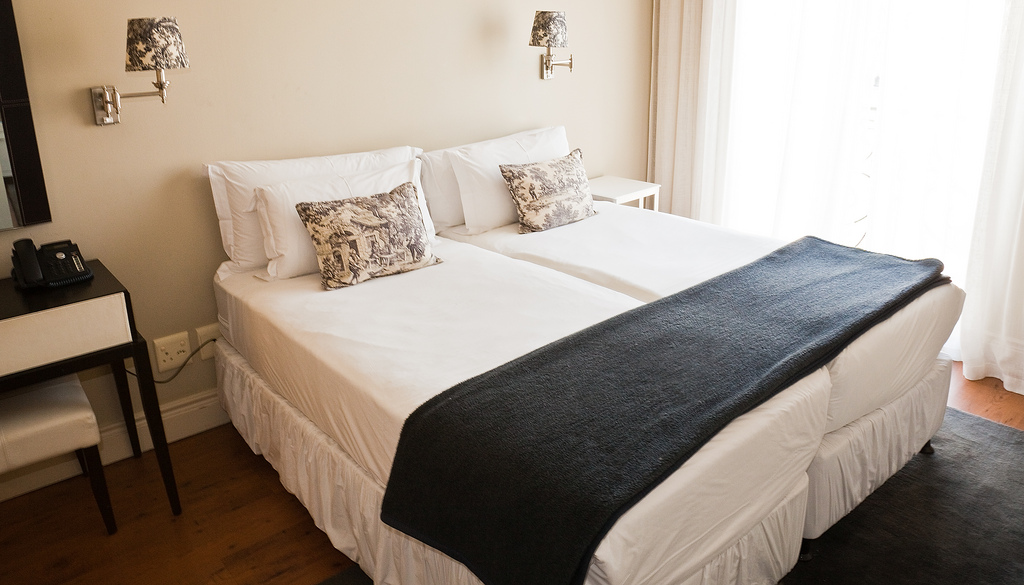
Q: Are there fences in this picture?
A: No, there are no fences.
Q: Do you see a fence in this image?
A: No, there are no fences.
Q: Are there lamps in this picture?
A: Yes, there is a lamp.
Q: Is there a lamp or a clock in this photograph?
A: Yes, there is a lamp.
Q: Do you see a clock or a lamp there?
A: Yes, there is a lamp.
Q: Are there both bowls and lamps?
A: No, there is a lamp but no bowls.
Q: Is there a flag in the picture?
A: No, there are no flags.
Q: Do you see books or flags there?
A: No, there are no flags or books.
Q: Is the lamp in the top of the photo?
A: Yes, the lamp is in the top of the image.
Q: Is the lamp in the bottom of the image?
A: No, the lamp is in the top of the image.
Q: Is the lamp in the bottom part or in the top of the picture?
A: The lamp is in the top of the image.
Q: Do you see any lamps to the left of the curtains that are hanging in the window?
A: Yes, there is a lamp to the left of the curtains.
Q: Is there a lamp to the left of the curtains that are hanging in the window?
A: Yes, there is a lamp to the left of the curtains.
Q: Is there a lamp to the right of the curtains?
A: No, the lamp is to the left of the curtains.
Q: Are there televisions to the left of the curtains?
A: No, there is a lamp to the left of the curtains.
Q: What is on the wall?
A: The lamp is on the wall.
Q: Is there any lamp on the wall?
A: Yes, there is a lamp on the wall.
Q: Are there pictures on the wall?
A: No, there is a lamp on the wall.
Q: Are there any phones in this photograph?
A: Yes, there is a phone.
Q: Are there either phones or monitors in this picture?
A: Yes, there is a phone.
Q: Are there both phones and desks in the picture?
A: Yes, there are both a phone and a desk.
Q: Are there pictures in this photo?
A: No, there are no pictures.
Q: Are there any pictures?
A: No, there are no pictures.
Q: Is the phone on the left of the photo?
A: Yes, the phone is on the left of the image.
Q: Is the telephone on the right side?
A: No, the telephone is on the left of the image.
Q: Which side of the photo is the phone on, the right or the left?
A: The phone is on the left of the image.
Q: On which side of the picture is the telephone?
A: The telephone is on the left of the image.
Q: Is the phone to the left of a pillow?
A: Yes, the phone is to the left of a pillow.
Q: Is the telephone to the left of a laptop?
A: No, the telephone is to the left of a pillow.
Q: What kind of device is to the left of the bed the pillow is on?
A: The device is a phone.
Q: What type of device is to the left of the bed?
A: The device is a phone.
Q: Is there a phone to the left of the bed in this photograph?
A: Yes, there is a phone to the left of the bed.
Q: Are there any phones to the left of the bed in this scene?
A: Yes, there is a phone to the left of the bed.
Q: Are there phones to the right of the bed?
A: No, the phone is to the left of the bed.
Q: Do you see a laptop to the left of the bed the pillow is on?
A: No, there is a phone to the left of the bed.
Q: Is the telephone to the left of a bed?
A: Yes, the telephone is to the left of a bed.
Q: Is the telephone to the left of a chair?
A: No, the telephone is to the left of a bed.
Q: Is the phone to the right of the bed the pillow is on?
A: No, the phone is to the left of the bed.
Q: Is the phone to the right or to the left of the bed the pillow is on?
A: The phone is to the left of the bed.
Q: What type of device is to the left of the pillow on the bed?
A: The device is a phone.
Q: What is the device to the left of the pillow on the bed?
A: The device is a phone.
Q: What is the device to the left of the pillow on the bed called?
A: The device is a phone.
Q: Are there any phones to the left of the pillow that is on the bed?
A: Yes, there is a phone to the left of the pillow.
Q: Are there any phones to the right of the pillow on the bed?
A: No, the phone is to the left of the pillow.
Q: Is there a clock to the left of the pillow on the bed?
A: No, there is a phone to the left of the pillow.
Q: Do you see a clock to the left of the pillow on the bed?
A: No, there is a phone to the left of the pillow.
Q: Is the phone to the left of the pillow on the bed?
A: Yes, the phone is to the left of the pillow.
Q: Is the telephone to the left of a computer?
A: No, the telephone is to the left of the pillow.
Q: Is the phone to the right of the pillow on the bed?
A: No, the phone is to the left of the pillow.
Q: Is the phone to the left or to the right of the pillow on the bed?
A: The phone is to the left of the pillow.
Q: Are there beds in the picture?
A: Yes, there is a bed.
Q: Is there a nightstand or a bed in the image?
A: Yes, there is a bed.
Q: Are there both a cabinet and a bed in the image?
A: No, there is a bed but no cabinets.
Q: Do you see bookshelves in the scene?
A: No, there are no bookshelves.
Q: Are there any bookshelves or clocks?
A: No, there are no bookshelves or clocks.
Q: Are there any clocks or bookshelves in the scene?
A: No, there are no bookshelves or clocks.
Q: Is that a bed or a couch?
A: That is a bed.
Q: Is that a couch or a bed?
A: That is a bed.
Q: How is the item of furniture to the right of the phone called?
A: The piece of furniture is a bed.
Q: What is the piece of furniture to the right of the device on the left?
A: The piece of furniture is a bed.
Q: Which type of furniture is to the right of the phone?
A: The piece of furniture is a bed.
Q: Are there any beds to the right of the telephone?
A: Yes, there is a bed to the right of the telephone.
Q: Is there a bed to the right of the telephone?
A: Yes, there is a bed to the right of the telephone.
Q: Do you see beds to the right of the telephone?
A: Yes, there is a bed to the right of the telephone.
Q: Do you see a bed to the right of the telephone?
A: Yes, there is a bed to the right of the telephone.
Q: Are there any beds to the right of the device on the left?
A: Yes, there is a bed to the right of the telephone.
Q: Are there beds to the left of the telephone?
A: No, the bed is to the right of the telephone.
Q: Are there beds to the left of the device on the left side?
A: No, the bed is to the right of the telephone.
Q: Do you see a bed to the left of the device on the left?
A: No, the bed is to the right of the telephone.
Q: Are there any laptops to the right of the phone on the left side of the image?
A: No, there is a bed to the right of the telephone.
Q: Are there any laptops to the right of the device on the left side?
A: No, there is a bed to the right of the telephone.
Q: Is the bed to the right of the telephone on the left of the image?
A: Yes, the bed is to the right of the telephone.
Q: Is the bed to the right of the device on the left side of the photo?
A: Yes, the bed is to the right of the telephone.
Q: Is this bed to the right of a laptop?
A: No, the bed is to the right of the telephone.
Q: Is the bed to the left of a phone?
A: No, the bed is to the right of a phone.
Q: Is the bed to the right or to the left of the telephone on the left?
A: The bed is to the right of the phone.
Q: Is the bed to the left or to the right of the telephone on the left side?
A: The bed is to the right of the phone.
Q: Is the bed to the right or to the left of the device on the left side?
A: The bed is to the right of the phone.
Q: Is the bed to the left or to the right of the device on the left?
A: The bed is to the right of the phone.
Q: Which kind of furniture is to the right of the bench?
A: The piece of furniture is a bed.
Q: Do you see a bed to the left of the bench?
A: No, the bed is to the right of the bench.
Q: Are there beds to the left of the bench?
A: No, the bed is to the right of the bench.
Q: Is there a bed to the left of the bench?
A: No, the bed is to the right of the bench.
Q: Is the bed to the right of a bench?
A: Yes, the bed is to the right of a bench.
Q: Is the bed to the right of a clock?
A: No, the bed is to the right of a bench.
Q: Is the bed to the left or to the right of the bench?
A: The bed is to the right of the bench.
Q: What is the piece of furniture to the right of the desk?
A: The piece of furniture is a bed.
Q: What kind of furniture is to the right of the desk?
A: The piece of furniture is a bed.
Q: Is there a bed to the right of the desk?
A: Yes, there is a bed to the right of the desk.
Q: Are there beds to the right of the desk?
A: Yes, there is a bed to the right of the desk.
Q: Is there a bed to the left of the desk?
A: No, the bed is to the right of the desk.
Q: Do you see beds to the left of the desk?
A: No, the bed is to the right of the desk.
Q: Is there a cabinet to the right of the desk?
A: No, there is a bed to the right of the desk.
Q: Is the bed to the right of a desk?
A: Yes, the bed is to the right of a desk.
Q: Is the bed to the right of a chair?
A: No, the bed is to the right of a desk.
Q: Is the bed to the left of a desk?
A: No, the bed is to the right of a desk.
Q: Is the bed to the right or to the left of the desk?
A: The bed is to the right of the desk.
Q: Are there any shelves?
A: No, there are no shelves.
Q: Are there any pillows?
A: Yes, there is a pillow.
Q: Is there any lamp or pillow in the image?
A: Yes, there is a pillow.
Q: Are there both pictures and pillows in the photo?
A: No, there is a pillow but no pictures.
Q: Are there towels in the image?
A: No, there are no towels.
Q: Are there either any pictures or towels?
A: No, there are no towels or pictures.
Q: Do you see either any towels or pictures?
A: No, there are no towels or pictures.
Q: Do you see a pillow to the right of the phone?
A: Yes, there is a pillow to the right of the phone.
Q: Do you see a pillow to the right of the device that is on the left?
A: Yes, there is a pillow to the right of the phone.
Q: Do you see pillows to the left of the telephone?
A: No, the pillow is to the right of the telephone.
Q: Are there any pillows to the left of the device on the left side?
A: No, the pillow is to the right of the telephone.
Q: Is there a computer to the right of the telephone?
A: No, there is a pillow to the right of the telephone.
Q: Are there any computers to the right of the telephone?
A: No, there is a pillow to the right of the telephone.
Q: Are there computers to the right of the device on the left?
A: No, there is a pillow to the right of the telephone.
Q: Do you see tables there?
A: Yes, there is a table.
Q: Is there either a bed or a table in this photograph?
A: Yes, there is a table.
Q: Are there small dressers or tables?
A: Yes, there is a small table.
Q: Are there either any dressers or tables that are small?
A: Yes, the table is small.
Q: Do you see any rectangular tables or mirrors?
A: Yes, there is a rectangular table.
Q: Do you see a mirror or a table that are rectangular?
A: Yes, the table is rectangular.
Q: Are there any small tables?
A: Yes, there is a small table.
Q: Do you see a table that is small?
A: Yes, there is a table that is small.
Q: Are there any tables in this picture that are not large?
A: Yes, there is a small table.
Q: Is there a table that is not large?
A: Yes, there is a small table.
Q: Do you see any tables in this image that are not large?
A: Yes, there is a small table.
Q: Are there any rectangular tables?
A: Yes, there is a rectangular table.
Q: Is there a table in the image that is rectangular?
A: Yes, there is a table that is rectangular.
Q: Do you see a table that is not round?
A: Yes, there is a rectangular table.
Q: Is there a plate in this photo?
A: No, there are no plates.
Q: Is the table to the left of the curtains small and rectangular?
A: Yes, the table is small and rectangular.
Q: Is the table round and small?
A: No, the table is small but rectangular.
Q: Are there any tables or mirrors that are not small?
A: No, there is a table but it is small.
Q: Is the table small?
A: Yes, the table is small.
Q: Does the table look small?
A: Yes, the table is small.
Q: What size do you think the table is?
A: The table is small.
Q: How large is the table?
A: The table is small.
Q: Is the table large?
A: No, the table is small.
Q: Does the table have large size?
A: No, the table is small.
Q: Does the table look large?
A: No, the table is small.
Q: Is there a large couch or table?
A: No, there is a table but it is small.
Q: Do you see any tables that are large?
A: No, there is a table but it is small.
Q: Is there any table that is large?
A: No, there is a table but it is small.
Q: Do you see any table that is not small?
A: No, there is a table but it is small.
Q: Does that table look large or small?
A: The table is small.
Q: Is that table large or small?
A: The table is small.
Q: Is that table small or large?
A: The table is small.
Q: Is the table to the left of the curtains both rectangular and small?
A: Yes, the table is rectangular and small.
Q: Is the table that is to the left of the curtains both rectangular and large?
A: No, the table is rectangular but small.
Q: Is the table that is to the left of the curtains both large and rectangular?
A: No, the table is rectangular but small.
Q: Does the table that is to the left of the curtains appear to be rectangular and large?
A: No, the table is rectangular but small.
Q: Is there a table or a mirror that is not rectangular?
A: No, there is a table but it is rectangular.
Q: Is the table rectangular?
A: Yes, the table is rectangular.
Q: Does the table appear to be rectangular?
A: Yes, the table is rectangular.